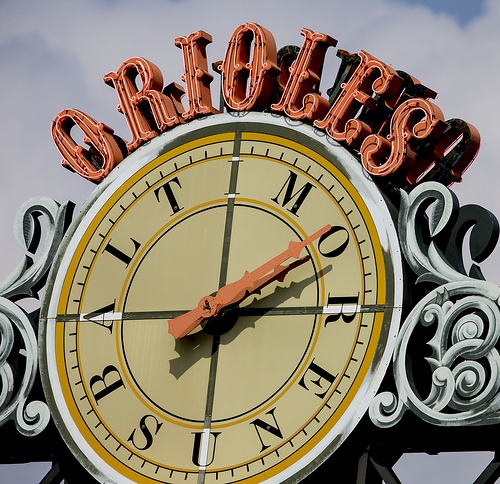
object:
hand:
[170, 222, 337, 338]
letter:
[356, 97, 442, 179]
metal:
[403, 294, 498, 415]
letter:
[270, 167, 320, 215]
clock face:
[25, 42, 429, 476]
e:
[293, 356, 343, 411]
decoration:
[372, 179, 495, 430]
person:
[33, 102, 409, 478]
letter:
[86, 360, 126, 405]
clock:
[24, 35, 433, 482]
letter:
[173, 30, 218, 120]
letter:
[146, 172, 192, 217]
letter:
[315, 291, 365, 323]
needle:
[171, 222, 333, 344]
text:
[49, 19, 476, 193]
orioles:
[49, 23, 447, 181]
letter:
[144, 172, 184, 221]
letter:
[97, 230, 144, 269]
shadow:
[157, 264, 346, 382]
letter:
[247, 405, 294, 466]